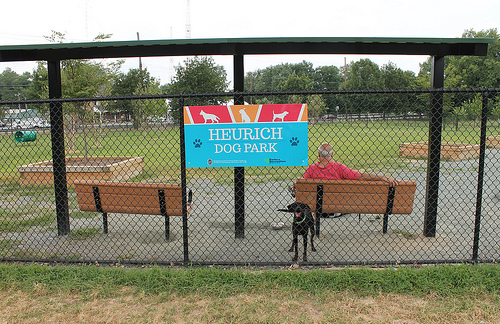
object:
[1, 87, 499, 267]
fence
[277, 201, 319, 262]
dog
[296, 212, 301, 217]
tongue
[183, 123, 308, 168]
sign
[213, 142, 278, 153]
dog park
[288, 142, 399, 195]
man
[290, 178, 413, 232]
bench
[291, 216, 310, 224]
collar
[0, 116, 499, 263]
park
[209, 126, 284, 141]
heurich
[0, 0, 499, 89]
sky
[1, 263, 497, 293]
grass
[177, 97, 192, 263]
post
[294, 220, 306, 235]
chest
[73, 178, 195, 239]
bench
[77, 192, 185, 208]
slat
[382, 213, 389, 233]
leg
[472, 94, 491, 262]
post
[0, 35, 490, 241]
ramada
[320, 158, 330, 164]
neck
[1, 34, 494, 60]
roof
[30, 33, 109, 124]
tree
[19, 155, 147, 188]
planter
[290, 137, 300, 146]
icon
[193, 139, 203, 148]
icon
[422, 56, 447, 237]
post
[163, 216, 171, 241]
leg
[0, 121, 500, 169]
grass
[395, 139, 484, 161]
planter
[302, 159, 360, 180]
shirt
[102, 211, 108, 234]
leg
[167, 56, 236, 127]
tree